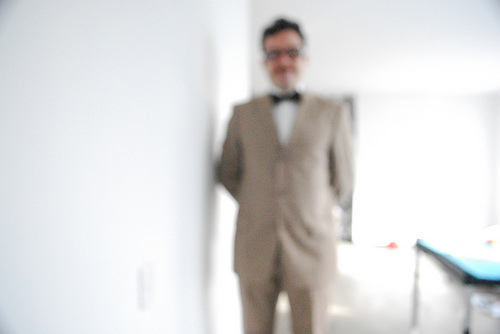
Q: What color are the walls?
A: White.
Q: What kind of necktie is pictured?
A: A bowtie.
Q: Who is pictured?
A: A man.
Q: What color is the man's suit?
A: Beige.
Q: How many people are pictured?
A: One.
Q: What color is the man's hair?
A: Black.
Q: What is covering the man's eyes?
A: Glasses.